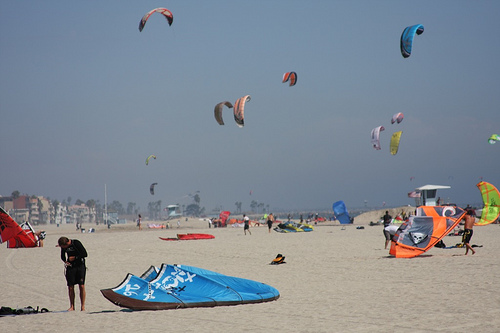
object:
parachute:
[102, 261, 278, 309]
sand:
[313, 240, 356, 275]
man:
[52, 235, 90, 313]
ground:
[1, 250, 28, 300]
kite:
[394, 14, 427, 64]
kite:
[141, 147, 162, 172]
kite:
[132, 5, 183, 34]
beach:
[419, 311, 499, 331]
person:
[48, 231, 98, 316]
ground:
[484, 234, 500, 273]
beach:
[260, 318, 299, 332]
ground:
[312, 278, 378, 298]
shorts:
[65, 260, 88, 286]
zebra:
[65, 245, 81, 256]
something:
[61, 260, 73, 276]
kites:
[407, 172, 424, 184]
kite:
[211, 98, 234, 128]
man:
[383, 223, 403, 251]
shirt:
[384, 224, 401, 237]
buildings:
[2, 190, 41, 225]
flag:
[407, 189, 425, 207]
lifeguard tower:
[417, 181, 451, 208]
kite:
[279, 70, 301, 91]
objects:
[211, 205, 231, 229]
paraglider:
[223, 89, 258, 133]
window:
[427, 190, 436, 198]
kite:
[141, 175, 161, 201]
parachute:
[474, 175, 498, 229]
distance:
[292, 198, 336, 223]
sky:
[1, 0, 29, 173]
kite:
[388, 125, 404, 155]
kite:
[370, 120, 385, 149]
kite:
[388, 108, 405, 125]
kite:
[388, 204, 464, 258]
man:
[461, 203, 476, 257]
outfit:
[240, 211, 257, 237]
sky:
[130, 7, 198, 103]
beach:
[340, 321, 427, 332]